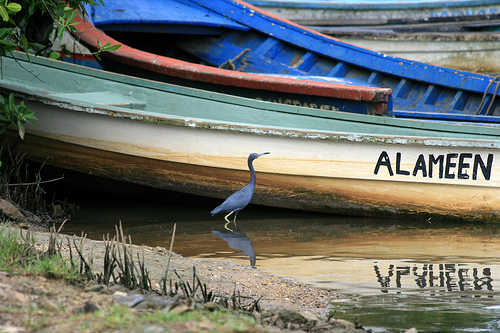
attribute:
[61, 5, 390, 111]
trim — red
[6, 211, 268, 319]
plants — spiky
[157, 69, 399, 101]
edge — red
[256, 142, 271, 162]
beak — long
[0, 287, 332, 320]
shore line — sandy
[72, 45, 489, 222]
canoe — green, white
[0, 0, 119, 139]
leaves — green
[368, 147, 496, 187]
word — black, hand painted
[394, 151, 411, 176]
l — black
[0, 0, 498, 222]
boat — algae covered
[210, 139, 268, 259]
heron — blue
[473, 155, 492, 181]
letter — black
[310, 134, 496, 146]
paint — worn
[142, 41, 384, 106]
paint — worn, red